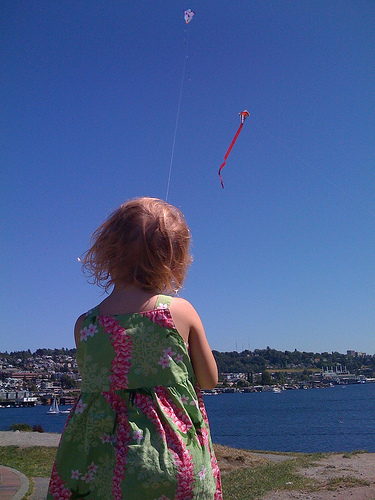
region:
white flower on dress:
[154, 353, 175, 371]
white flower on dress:
[162, 345, 178, 358]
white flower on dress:
[172, 352, 188, 364]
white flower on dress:
[174, 391, 191, 410]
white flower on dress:
[84, 322, 102, 337]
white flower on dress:
[77, 322, 89, 345]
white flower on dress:
[74, 396, 91, 416]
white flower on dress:
[68, 467, 80, 483]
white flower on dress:
[78, 469, 96, 485]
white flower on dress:
[84, 461, 102, 473]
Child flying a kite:
[43, 7, 253, 485]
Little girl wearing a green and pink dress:
[42, 201, 208, 495]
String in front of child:
[135, 37, 202, 189]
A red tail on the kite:
[202, 115, 247, 186]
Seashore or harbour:
[0, 400, 63, 427]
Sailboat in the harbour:
[36, 392, 70, 420]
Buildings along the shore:
[225, 361, 362, 393]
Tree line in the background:
[225, 333, 341, 365]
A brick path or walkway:
[1, 448, 25, 498]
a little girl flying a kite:
[74, 187, 245, 494]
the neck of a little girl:
[106, 274, 142, 298]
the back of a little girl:
[79, 287, 186, 381]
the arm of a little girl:
[185, 305, 225, 381]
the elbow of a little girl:
[188, 364, 223, 397]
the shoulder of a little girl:
[163, 287, 196, 319]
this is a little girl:
[40, 135, 262, 499]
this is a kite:
[173, 3, 224, 50]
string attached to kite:
[150, 17, 202, 210]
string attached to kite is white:
[163, 25, 205, 209]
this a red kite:
[195, 76, 275, 214]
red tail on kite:
[213, 119, 253, 193]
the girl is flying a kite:
[40, 9, 270, 498]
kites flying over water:
[108, 8, 371, 467]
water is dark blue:
[23, 340, 366, 462]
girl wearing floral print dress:
[53, 283, 218, 496]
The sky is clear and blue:
[25, 8, 142, 141]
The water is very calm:
[249, 386, 366, 456]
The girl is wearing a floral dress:
[38, 299, 221, 495]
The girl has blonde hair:
[64, 190, 208, 296]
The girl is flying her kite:
[45, 5, 228, 498]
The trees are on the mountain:
[219, 336, 364, 375]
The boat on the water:
[37, 389, 70, 417]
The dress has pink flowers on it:
[102, 324, 133, 497]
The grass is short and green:
[229, 465, 283, 498]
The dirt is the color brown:
[317, 452, 371, 498]